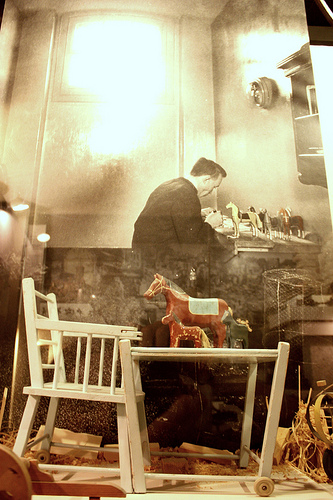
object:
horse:
[144, 272, 233, 349]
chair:
[9, 276, 151, 494]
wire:
[302, 391, 332, 448]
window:
[53, 10, 178, 108]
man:
[130, 132, 229, 278]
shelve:
[276, 31, 323, 188]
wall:
[1, 83, 34, 201]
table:
[202, 209, 314, 340]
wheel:
[254, 474, 274, 496]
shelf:
[46, 122, 135, 218]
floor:
[152, 478, 249, 499]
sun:
[91, 48, 179, 128]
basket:
[265, 367, 333, 488]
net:
[262, 266, 327, 365]